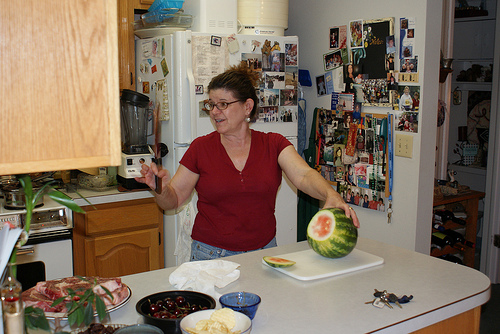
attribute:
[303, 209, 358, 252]
watermelon — cut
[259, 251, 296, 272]
end — cut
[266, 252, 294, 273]
rind — cut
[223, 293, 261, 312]
bowl — blue, small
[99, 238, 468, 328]
countertop — white, large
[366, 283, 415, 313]
keys — set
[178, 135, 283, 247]
shirt — red, maroon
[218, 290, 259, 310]
glass — blue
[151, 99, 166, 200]
knife — large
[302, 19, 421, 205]
collection — large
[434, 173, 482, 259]
rack — wood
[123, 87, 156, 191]
blender — sitting, large, black, white, empty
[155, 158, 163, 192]
handle — black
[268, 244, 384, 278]
cutting board — plastic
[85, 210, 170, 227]
drawer — brown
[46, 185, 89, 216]
leaf — green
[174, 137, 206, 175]
sleeve — short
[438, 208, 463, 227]
bottle — large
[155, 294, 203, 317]
cherries — dark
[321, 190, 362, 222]
hand — resting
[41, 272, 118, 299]
meat — raw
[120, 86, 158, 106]
lid — askew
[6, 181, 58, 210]
pan — silver